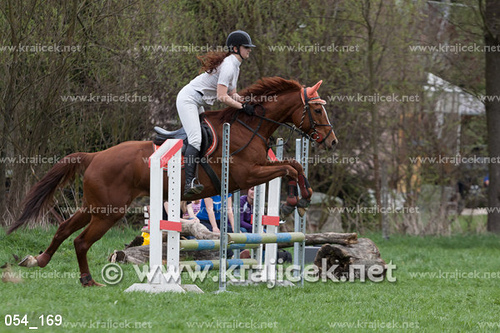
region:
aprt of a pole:
[242, 218, 296, 303]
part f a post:
[170, 229, 187, 271]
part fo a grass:
[391, 276, 420, 316]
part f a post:
[154, 206, 193, 303]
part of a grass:
[391, 263, 410, 293]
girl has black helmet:
[224, 29, 264, 56]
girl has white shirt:
[182, 58, 257, 107]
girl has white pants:
[164, 84, 202, 145]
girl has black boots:
[174, 144, 216, 211]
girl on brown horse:
[47, 42, 303, 274]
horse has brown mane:
[220, 62, 310, 104]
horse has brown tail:
[20, 144, 102, 230]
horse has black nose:
[319, 129, 344, 156]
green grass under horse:
[90, 299, 260, 330]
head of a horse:
[277, 79, 353, 149]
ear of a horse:
[308, 68, 348, 99]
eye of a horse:
[312, 99, 328, 114]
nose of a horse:
[325, 131, 350, 144]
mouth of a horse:
[322, 141, 339, 152]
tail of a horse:
[11, 148, 82, 225]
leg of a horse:
[29, 196, 88, 278]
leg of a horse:
[73, 214, 137, 282]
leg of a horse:
[245, 156, 305, 201]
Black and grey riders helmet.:
[223, 31, 257, 51]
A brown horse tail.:
[5, 151, 93, 234]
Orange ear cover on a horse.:
[308, 77, 322, 98]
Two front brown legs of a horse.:
[251, 159, 312, 219]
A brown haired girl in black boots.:
[176, 30, 255, 198]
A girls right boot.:
[181, 142, 206, 199]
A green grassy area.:
[3, 224, 498, 331]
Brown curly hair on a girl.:
[195, 46, 230, 73]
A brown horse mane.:
[220, 76, 305, 123]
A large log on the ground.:
[314, 238, 384, 279]